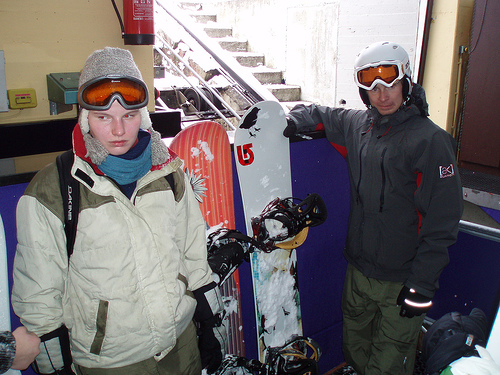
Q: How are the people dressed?
A: Winter.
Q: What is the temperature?
A: Cold.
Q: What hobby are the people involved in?
A: Snowboarding.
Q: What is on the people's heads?
A: Goggles.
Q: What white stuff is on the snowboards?
A: Snow.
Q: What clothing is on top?
A: Jackets.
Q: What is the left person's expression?
A: Frown.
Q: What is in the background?
A: Staircase.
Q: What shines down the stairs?
A: Sun.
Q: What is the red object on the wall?
A: Fire hydrant.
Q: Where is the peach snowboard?
A: Next to the white snowboard.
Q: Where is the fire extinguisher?
A: On the wall.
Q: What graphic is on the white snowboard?
A: A black bird.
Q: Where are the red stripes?
A: On the grey jacket.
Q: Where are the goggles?
A: On the skiers heads.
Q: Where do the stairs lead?
A: Up the hill.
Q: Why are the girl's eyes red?
A: Bad camera flash.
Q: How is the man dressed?
A: For cold weather.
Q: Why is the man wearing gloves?
A: To keep his hands warm.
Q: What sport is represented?
A: Snowboarding.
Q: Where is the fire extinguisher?
A: On wall.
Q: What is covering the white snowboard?
A: Snow.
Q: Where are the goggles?
A: On top of people's heads.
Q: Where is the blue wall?
A: Behind snowboarders.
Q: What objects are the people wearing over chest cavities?
A: Ski jackets.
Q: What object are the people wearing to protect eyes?
A: Snow goggles.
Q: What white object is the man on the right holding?
A: Snowboard.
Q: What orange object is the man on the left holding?
A: Snowboard.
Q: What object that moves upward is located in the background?
A: Staircase.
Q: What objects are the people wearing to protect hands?
A: Gloves.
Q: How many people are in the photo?
A: Two.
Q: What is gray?
A: A hat.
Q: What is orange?
A: Two goggles.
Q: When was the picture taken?
A: Daytime.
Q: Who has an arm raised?
A: Man on right.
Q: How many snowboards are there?
A: Two.